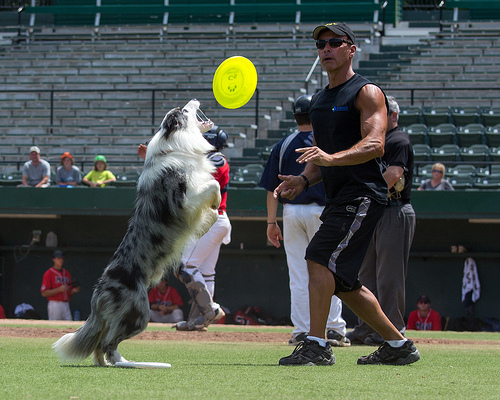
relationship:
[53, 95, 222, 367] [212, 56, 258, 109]
dog catching frisbee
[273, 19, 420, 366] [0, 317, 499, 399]
man standing on grass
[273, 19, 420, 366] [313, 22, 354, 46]
man wearing hat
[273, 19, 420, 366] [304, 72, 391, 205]
man wearing shirt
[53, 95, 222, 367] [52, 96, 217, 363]
dog has long coat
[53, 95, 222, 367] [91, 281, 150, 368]
dog standing on hind legs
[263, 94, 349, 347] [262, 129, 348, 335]
person in baseball uniform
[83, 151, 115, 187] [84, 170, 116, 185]
person wearing shirt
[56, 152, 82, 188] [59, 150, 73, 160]
person wearing hat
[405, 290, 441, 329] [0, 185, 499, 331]
person sitting in dugout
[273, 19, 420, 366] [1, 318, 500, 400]
man standing on field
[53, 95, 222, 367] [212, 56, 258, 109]
dog trying to catch frisbee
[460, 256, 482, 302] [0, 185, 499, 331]
towel hung in dugout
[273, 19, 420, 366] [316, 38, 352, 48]
man wearing sunglasses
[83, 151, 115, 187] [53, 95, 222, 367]
person watching dog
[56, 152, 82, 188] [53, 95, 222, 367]
person watching dog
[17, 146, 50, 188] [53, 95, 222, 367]
person watching dog